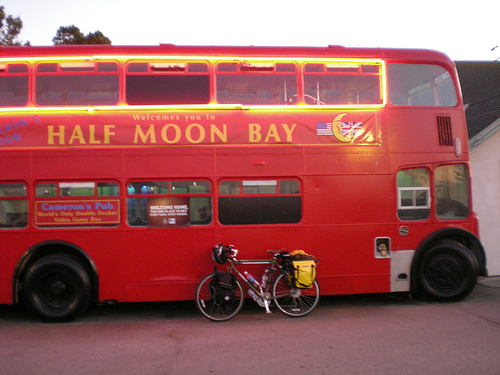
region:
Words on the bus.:
[33, 103, 468, 203]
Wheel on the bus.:
[381, 224, 496, 320]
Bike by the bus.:
[168, 223, 335, 340]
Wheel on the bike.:
[198, 259, 235, 313]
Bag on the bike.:
[277, 235, 362, 307]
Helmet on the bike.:
[216, 240, 236, 273]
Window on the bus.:
[125, 173, 250, 253]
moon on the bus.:
[316, 99, 405, 165]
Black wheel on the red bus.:
[392, 211, 491, 318]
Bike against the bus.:
[179, 228, 449, 371]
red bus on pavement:
[1, 35, 490, 334]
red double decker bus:
[0, 32, 494, 329]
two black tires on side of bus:
[12, 235, 482, 328]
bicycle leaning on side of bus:
[180, 234, 332, 328]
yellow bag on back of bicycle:
[282, 254, 319, 292]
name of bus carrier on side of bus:
[39, 119, 301, 155]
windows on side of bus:
[0, 53, 459, 123]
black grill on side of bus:
[429, 109, 460, 149]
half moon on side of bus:
[324, 109, 361, 156]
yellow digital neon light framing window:
[2, 53, 389, 120]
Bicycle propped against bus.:
[188, 244, 333, 322]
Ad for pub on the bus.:
[25, 187, 132, 232]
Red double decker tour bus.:
[0, 37, 492, 309]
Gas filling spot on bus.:
[360, 231, 402, 266]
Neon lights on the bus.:
[0, 52, 387, 111]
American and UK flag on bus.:
[310, 111, 383, 150]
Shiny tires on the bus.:
[16, 243, 101, 321]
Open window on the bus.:
[212, 162, 323, 233]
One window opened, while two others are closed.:
[119, 53, 391, 112]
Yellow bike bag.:
[277, 245, 319, 291]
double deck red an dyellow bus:
[16, 26, 463, 258]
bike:
[203, 231, 325, 322]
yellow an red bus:
[15, 33, 453, 253]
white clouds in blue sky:
[129, 12, 167, 39]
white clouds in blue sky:
[459, 14, 476, 40]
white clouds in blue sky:
[312, 12, 339, 39]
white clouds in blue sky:
[354, 5, 389, 37]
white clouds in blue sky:
[223, 5, 257, 34]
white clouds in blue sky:
[272, 2, 316, 37]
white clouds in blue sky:
[150, 3, 189, 31]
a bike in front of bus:
[202, 215, 374, 335]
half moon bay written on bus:
[34, 109, 334, 156]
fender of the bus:
[398, 228, 486, 264]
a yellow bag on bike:
[280, 244, 330, 299]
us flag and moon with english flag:
[303, 103, 368, 164]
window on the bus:
[386, 165, 472, 248]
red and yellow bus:
[13, 39, 497, 258]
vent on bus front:
[431, 111, 473, 156]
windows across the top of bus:
[11, 59, 467, 107]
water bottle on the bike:
[243, 260, 268, 300]